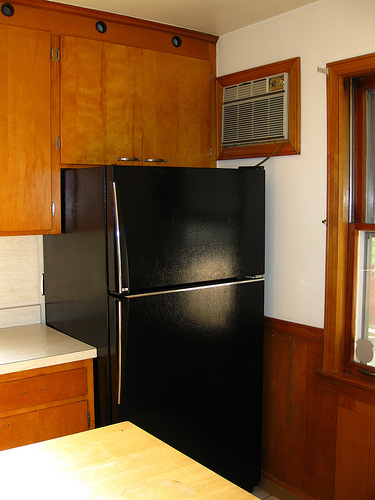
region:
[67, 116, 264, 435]
this is a kitchen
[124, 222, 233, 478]
this is a fridge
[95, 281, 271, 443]
the fridge is black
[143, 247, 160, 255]
this is a freezer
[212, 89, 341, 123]
this is an ac unit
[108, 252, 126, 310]
this is a handle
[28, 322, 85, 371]
this is a countertop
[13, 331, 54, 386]
the countertop is white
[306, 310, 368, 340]
this is a window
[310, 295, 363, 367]
the windowsill is wooden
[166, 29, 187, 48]
Black and clear light on a cabinet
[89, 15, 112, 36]
Black and clear light on a cabinet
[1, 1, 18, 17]
Black and clear light on a cabinet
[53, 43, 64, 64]
Small metal door henge on a wooden cabinet door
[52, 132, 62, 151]
Small metal door henge on a wooden cabinet door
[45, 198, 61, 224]
Small metal door henge on a wooden cabinet door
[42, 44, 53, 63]
Small metal door henge on a wooden cabinet door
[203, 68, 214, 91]
Small metal door henge on a wooden cabinet door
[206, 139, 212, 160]
Small metal door henge on a wooden cabinet door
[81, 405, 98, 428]
Small metal door henge on a wooden cabinet door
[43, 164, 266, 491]
The fridge is black.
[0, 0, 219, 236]
The cabinet is made of brown wood.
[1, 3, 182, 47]
Three round circles are black.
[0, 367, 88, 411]
Two holes are in the board.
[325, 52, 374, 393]
The window has a wood frame.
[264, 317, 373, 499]
Wood is on the wall.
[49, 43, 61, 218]
The four hinges are silver.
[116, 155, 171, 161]
Two handles are chrome.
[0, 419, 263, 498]
The tabletop is yellow.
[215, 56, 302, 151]
An air conditioner is in a wall frame.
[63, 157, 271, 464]
the refrigerator is black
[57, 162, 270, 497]
the refrigerator is black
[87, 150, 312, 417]
the refrigerator is black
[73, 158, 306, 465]
the refrigerator is black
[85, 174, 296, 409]
the refrigerator is black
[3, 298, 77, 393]
the countertop is empty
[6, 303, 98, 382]
the countertop is empty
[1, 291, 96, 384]
the countertop is empty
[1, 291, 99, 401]
the countertop is empty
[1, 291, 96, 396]
the countertop is empty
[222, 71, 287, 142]
Window unit air conditioner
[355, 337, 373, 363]
Sticker placed on window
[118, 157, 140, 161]
Chrome handle on kitchen cabinet door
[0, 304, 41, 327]
Back splash for laminate counter top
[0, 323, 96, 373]
Laminate counter top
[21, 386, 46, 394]
Holes for missing handle on kitchen cabinet drawer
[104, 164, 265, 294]
Freezer door on refrigerator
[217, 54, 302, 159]
Wooden frame around air conditioner window unit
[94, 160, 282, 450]
A black fridge raider next to window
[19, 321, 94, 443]
A white and brown counter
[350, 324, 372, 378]
A sticker on a window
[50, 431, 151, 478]
A wooden countertop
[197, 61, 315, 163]
An air conditioner in the wall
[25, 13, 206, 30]
Black holes in the top of the cabin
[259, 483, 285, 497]
Tile floor that is white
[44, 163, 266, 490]
the refrigerator is black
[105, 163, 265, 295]
the handle on the freezer door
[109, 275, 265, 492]
the handle on the refrigerator door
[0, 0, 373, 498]
the refrigerator in the kitchen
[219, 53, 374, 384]
the air conditioner near the window